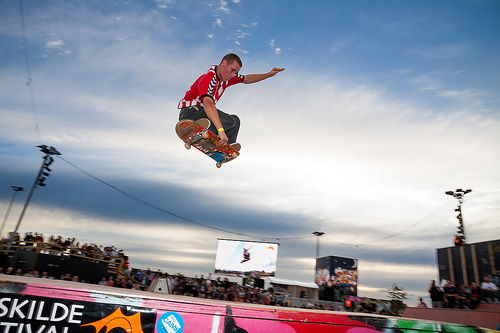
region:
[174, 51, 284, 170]
skateboarder flies through air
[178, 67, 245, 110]
shirt worn by human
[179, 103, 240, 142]
pants worn by human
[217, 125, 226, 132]
wrist band worn by human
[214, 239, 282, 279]
monitor behind human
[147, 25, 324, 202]
the guy in red shirt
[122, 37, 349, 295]
the guy in red shirt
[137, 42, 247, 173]
the guy in red shirt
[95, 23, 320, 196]
a guy in red shirt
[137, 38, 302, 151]
a guy in red shirt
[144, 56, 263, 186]
a guy in red shirt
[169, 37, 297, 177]
Skateboarder in the air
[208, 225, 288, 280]
Display screen of snowboarder in the air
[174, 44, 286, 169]
Skateboarder in a red shirt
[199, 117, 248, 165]
Hand gripping a skateboard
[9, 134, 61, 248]
Electrical pole to connect wires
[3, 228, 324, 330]
Crowd sitting in stands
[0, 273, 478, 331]
Wall to stands with advertisements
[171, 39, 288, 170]
Skateboarder with outstretched arm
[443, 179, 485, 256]
Electrical pole to connect wires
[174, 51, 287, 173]
Skateboarder wearing gray pants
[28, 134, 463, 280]
a wire